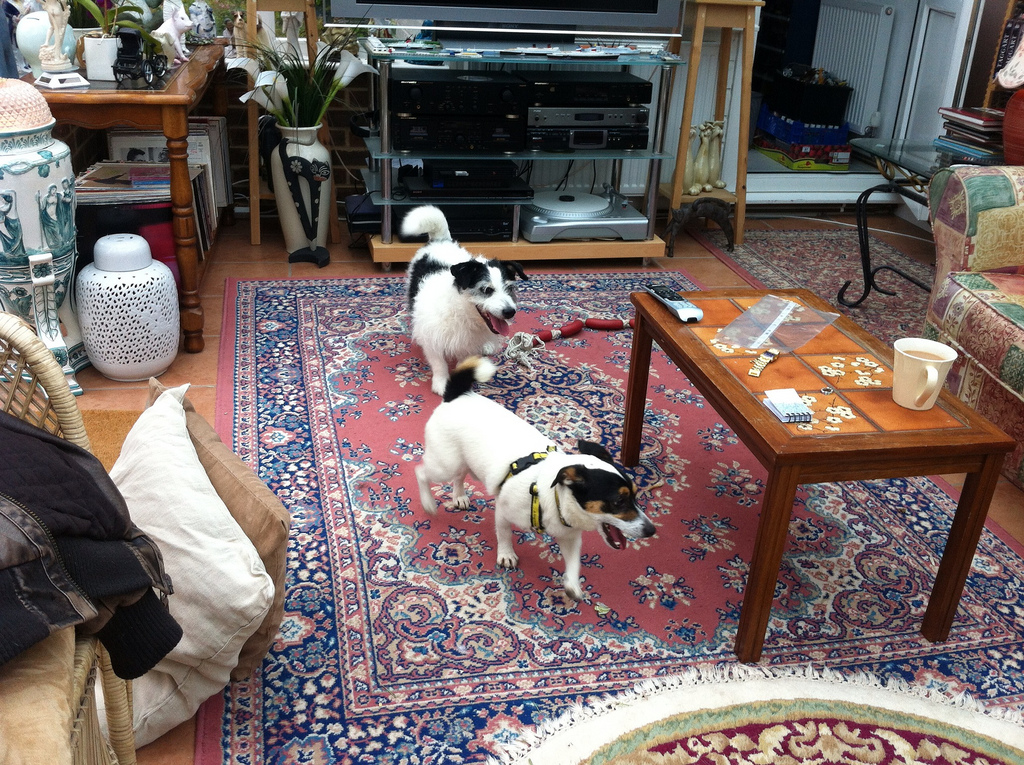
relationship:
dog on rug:
[414, 355, 657, 602] [276, 405, 363, 489]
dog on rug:
[374, 190, 553, 390] [232, 294, 426, 722]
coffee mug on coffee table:
[892, 338, 960, 411] [621, 290, 1020, 664]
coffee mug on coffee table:
[892, 338, 960, 411] [626, 279, 1019, 649]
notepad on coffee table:
[763, 380, 811, 432] [621, 290, 1020, 664]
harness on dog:
[489, 450, 565, 571] [411, 368, 666, 606]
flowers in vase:
[221, 50, 381, 140] [260, 107, 341, 267]